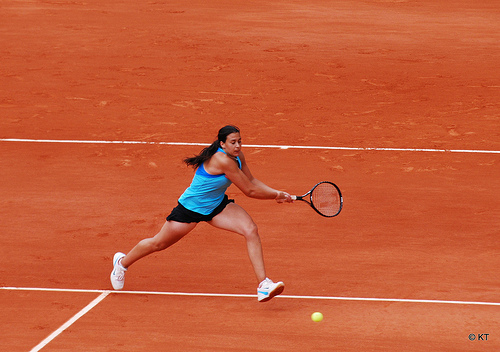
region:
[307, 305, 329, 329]
a yellow color tennis ball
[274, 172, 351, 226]
a woman holding tennis ball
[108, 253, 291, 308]
a lady wearing white color shoes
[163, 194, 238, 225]
a lady wearing black color shorts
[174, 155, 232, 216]
a woman wearing blue color t-shirt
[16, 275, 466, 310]
tennis court marked by white color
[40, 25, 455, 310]
woman is playing in tennis court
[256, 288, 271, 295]
blue color design in the shoe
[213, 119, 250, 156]
head of the woman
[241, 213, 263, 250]
knee of the woman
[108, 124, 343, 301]
A woman swinging a tennis rackett.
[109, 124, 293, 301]
A woman with dark hair.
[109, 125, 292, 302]
A woman wearing a blue top.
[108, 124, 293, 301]
A woman wearing black shorts.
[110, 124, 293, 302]
A woman wearing white shoes.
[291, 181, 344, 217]
A tennis rackett.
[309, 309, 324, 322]
A tennis ball.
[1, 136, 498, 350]
White lines painted on the tennis court.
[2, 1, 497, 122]
The tennis court is orange.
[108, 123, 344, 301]
The woman is about to hit the tennis ball.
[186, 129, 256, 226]
the shirt is blue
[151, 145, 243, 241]
the shirt is blue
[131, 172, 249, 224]
the short is black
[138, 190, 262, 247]
the short is black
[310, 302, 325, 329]
A tennis ball on the ground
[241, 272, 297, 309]
Blue and white shoes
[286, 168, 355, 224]
A tennis racket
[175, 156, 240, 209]
A blue top in the photo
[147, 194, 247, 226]
A black short skirt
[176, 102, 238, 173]
A long black hair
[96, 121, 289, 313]
A female tennis player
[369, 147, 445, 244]
A tennis court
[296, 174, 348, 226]
A black tennis court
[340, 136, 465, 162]
White markings in the photo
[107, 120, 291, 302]
Woman lunging her body forward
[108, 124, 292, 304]
Woman in athletic clothing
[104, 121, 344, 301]
Woman holding a tennis racket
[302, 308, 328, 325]
Tennis ball in the air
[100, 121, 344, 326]
Woman trying to hit a tennis ball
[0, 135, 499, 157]
White line on a tennis court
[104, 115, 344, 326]
Woman on a tennis court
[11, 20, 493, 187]
Footprints in the dirt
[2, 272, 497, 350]
White painted lines showing the court boundaries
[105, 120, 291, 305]
Woman with long brown hair